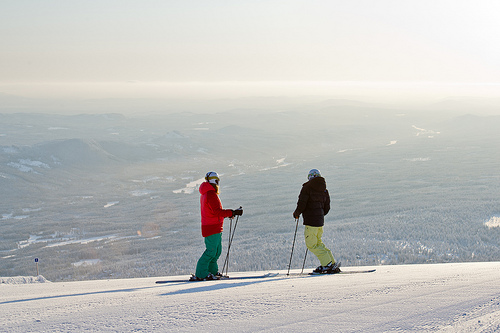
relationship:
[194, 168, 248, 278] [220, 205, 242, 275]
person holding ski poles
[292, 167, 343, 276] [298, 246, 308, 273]
person holding ski poles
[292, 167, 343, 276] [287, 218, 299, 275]
person holding poles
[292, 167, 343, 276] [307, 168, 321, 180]
person wearing hat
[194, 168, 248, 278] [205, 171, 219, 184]
person wearing hat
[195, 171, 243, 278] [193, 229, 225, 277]
person wearing green pants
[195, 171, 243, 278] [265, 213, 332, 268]
person holding ski poles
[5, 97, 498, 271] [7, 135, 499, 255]
mountains covered with snow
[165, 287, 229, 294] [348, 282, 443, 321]
shadow on ground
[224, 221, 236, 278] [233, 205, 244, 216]
ski pole in hand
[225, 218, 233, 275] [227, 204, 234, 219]
ski pole in hand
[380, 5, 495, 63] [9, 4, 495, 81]
light in sky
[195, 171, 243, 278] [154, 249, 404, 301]
person on snow skis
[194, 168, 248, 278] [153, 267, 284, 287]
person on skis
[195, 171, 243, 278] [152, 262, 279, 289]
person on skis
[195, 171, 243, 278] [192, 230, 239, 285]
person wearing pants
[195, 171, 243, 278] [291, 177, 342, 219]
person wearing jacket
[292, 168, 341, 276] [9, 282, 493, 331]
person on mountain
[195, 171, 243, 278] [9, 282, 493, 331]
person on mountain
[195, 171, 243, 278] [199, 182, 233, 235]
person wearing jacket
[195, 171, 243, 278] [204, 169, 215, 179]
person wearing a hat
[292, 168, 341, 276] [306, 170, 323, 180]
person wearing hat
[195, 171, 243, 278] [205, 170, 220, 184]
person wearing hat